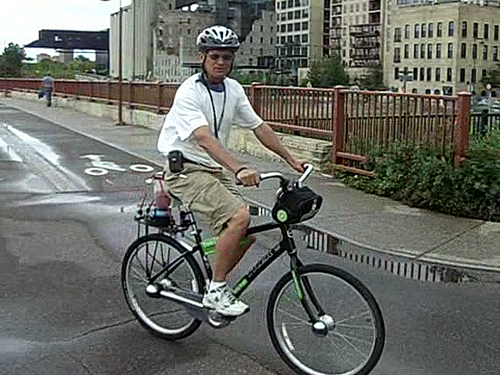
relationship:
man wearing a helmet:
[155, 24, 311, 323] [195, 22, 240, 49]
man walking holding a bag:
[32, 74, 143, 223] [14, 70, 66, 133]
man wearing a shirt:
[152, 24, 319, 317] [148, 66, 268, 173]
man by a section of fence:
[152, 24, 319, 317] [374, 95, 445, 151]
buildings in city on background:
[110, 0, 498, 114] [290, 53, 378, 100]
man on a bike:
[152, 24, 319, 317] [121, 162, 386, 374]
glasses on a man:
[203, 48, 234, 65] [183, 22, 253, 111]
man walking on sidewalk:
[39, 71, 56, 108] [8, 96, 496, 281]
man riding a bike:
[155, 24, 311, 323] [121, 162, 386, 374]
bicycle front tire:
[116, 156, 399, 373] [265, 272, 383, 375]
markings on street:
[79, 153, 154, 178] [0, 106, 499, 373]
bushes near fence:
[331, 134, 498, 222] [1, 69, 498, 191]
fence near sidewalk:
[6, 77, 485, 134] [8, 96, 496, 281]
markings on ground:
[78, 153, 155, 177] [347, 116, 437, 195]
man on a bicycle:
[155, 24, 311, 323] [116, 156, 399, 373]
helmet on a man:
[185, 22, 277, 64] [155, 24, 311, 323]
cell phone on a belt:
[168, 149, 183, 172] [183, 158, 194, 164]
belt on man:
[183, 158, 194, 164] [155, 24, 311, 323]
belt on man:
[183, 157, 194, 166] [155, 24, 311, 323]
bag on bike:
[271, 186, 323, 225] [121, 162, 386, 374]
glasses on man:
[209, 53, 234, 61] [155, 24, 311, 323]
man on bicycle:
[152, 24, 319, 317] [129, 165, 383, 370]